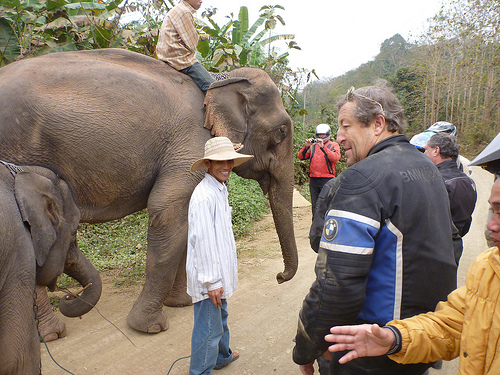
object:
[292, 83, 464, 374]
man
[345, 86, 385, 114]
glasses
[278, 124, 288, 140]
eye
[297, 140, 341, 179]
coat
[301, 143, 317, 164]
stripe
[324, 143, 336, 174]
stripe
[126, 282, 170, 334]
foot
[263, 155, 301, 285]
elephant trunk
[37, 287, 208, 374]
ground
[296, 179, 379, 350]
arm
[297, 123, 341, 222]
man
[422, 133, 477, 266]
man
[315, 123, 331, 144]
helmet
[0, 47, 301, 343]
elephant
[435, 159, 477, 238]
jacket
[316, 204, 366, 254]
part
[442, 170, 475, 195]
part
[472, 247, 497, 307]
part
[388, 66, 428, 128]
tree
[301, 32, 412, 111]
hill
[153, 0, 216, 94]
man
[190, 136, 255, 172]
hat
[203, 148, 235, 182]
head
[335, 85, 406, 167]
head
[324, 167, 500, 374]
man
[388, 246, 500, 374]
coat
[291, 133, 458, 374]
coat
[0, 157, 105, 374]
elephant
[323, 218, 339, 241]
logo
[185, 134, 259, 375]
man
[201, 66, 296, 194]
head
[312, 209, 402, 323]
design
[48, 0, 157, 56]
leaves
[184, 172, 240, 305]
shirt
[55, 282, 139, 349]
twig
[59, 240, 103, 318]
trunk